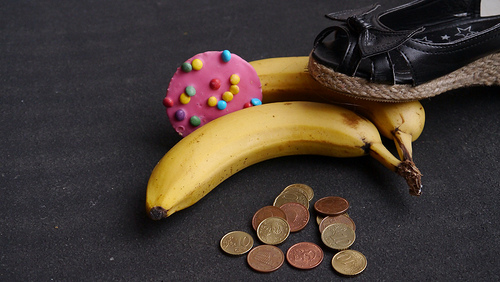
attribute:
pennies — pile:
[219, 177, 371, 279]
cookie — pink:
[160, 53, 265, 137]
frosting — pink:
[165, 51, 263, 131]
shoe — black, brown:
[305, 5, 497, 97]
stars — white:
[412, 14, 484, 57]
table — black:
[5, 5, 497, 265]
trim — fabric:
[301, 53, 498, 100]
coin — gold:
[251, 217, 293, 247]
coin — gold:
[282, 180, 319, 210]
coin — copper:
[330, 245, 376, 280]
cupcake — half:
[168, 47, 257, 82]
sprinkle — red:
[207, 72, 221, 92]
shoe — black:
[316, 20, 473, 85]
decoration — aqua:
[221, 48, 232, 64]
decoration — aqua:
[249, 96, 261, 106]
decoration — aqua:
[179, 61, 190, 71]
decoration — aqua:
[186, 85, 196, 97]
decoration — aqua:
[175, 109, 185, 121]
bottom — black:
[144, 196, 171, 220]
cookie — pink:
[138, 33, 254, 134]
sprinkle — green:
[185, 79, 203, 106]